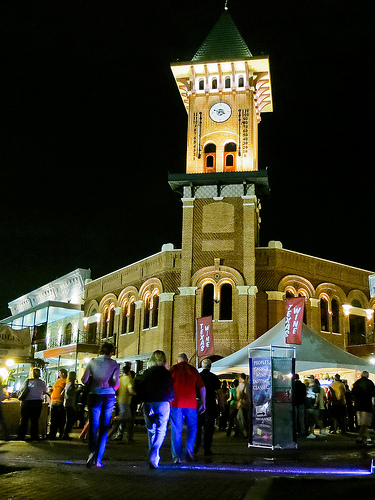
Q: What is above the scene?
A: A clock tower.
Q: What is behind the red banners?
A: White canopy.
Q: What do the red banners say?
A: Texas Wine.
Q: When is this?
A: At night.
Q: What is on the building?
A: Clock.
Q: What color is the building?
A: Brown.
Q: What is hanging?
A: Flags.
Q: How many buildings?
A: 1.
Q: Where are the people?
A: In front of the building.